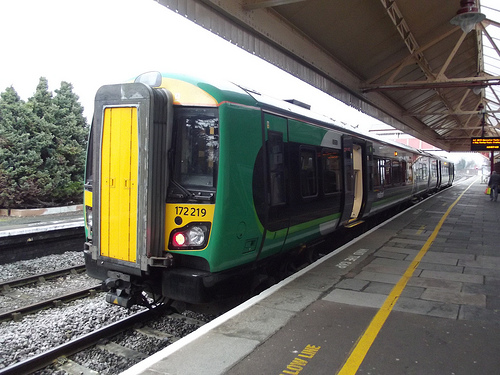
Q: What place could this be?
A: It is a station.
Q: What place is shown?
A: It is a station.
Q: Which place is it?
A: It is a station.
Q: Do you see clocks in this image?
A: No, there are no clocks.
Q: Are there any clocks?
A: No, there are no clocks.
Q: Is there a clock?
A: No, there are no clocks.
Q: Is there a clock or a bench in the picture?
A: No, there are no clocks or benches.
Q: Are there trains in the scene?
A: Yes, there is a train.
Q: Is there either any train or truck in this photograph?
A: Yes, there is a train.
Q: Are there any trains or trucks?
A: Yes, there is a train.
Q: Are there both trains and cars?
A: Yes, there are both a train and a car.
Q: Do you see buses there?
A: No, there are no buses.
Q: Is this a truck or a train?
A: This is a train.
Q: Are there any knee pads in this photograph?
A: No, there are no knee pads.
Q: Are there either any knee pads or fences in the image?
A: No, there are no knee pads or fences.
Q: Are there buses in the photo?
A: No, there are no buses.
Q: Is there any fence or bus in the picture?
A: No, there are no buses or fences.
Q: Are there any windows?
A: Yes, there are windows.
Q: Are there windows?
A: Yes, there are windows.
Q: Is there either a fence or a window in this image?
A: Yes, there are windows.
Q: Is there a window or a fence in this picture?
A: Yes, there are windows.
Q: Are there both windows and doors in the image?
A: Yes, there are both windows and a door.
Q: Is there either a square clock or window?
A: Yes, there are square windows.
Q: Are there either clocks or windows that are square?
A: Yes, the windows are square.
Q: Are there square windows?
A: Yes, there are square windows.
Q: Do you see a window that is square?
A: Yes, there are windows that are square.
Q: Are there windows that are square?
A: Yes, there are windows that are square.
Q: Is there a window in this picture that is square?
A: Yes, there are windows that are square.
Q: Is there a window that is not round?
A: Yes, there are square windows.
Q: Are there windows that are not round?
A: Yes, there are square windows.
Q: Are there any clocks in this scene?
A: No, there are no clocks.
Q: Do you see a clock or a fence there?
A: No, there are no clocks or fences.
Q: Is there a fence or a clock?
A: No, there are no clocks or fences.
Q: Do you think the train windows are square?
A: Yes, the windows are square.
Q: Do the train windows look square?
A: Yes, the windows are square.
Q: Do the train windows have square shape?
A: Yes, the windows are square.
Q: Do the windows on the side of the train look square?
A: Yes, the windows are square.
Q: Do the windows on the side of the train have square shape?
A: Yes, the windows are square.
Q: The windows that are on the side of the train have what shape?
A: The windows are square.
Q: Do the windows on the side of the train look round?
A: No, the windows are square.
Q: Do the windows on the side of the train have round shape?
A: No, the windows are square.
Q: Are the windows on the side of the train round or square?
A: The windows are square.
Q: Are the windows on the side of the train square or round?
A: The windows are square.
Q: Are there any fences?
A: No, there are no fences.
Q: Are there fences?
A: No, there are no fences.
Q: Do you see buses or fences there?
A: No, there are no fences or buses.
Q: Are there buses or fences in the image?
A: No, there are no fences or buses.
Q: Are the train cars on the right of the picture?
A: Yes, the cars are on the right of the image.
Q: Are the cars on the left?
A: No, the cars are on the right of the image.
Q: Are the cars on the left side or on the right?
A: The cars are on the right of the image.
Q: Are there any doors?
A: Yes, there is a door.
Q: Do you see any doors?
A: Yes, there is a door.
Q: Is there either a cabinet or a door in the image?
A: Yes, there is a door.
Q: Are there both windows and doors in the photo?
A: Yes, there are both a door and windows.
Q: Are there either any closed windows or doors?
A: Yes, there is a closed door.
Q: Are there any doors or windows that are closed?
A: Yes, the door is closed.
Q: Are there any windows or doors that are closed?
A: Yes, the door is closed.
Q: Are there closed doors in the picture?
A: Yes, there is a closed door.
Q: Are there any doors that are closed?
A: Yes, there is a door that is closed.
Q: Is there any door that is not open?
A: Yes, there is an closed door.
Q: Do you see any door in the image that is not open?
A: Yes, there is an closed door.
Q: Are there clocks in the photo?
A: No, there are no clocks.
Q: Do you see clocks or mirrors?
A: No, there are no clocks or mirrors.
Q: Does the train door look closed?
A: Yes, the door is closed.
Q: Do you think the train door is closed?
A: Yes, the door is closed.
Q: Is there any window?
A: Yes, there is a window.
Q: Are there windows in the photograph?
A: Yes, there is a window.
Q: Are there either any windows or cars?
A: Yes, there is a window.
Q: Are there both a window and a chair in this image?
A: No, there is a window but no chairs.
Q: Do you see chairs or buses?
A: No, there are no buses or chairs.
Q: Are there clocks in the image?
A: No, there are no clocks.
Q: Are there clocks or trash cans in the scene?
A: No, there are no clocks or trash cans.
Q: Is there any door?
A: Yes, there is a door.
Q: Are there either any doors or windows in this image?
A: Yes, there is a door.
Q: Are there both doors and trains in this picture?
A: Yes, there are both a door and a train.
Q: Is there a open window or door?
A: Yes, there is an open door.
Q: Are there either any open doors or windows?
A: Yes, there is an open door.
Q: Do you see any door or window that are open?
A: Yes, the door is open.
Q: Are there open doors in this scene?
A: Yes, there is an open door.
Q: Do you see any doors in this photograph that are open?
A: Yes, there is an open door.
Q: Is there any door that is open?
A: Yes, there is a door that is open.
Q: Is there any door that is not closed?
A: Yes, there is a open door.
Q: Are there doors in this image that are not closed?
A: Yes, there is a open door.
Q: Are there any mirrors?
A: No, there are no mirrors.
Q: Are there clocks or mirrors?
A: No, there are no mirrors or clocks.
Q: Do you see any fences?
A: No, there are no fences.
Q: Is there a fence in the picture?
A: No, there are no fences.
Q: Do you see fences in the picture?
A: No, there are no fences.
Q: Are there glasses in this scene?
A: No, there are no glasses.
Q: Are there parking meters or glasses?
A: No, there are no glasses or parking meters.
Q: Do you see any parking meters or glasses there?
A: No, there are no glasses or parking meters.